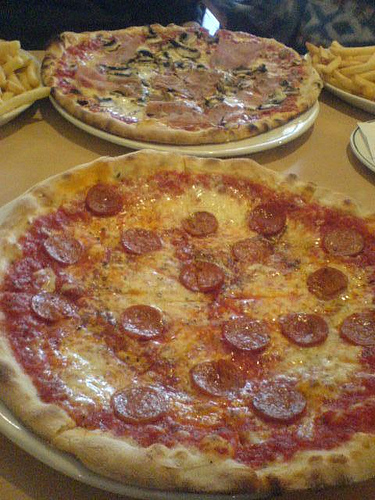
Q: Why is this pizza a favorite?
A: Pepperoni and cheese.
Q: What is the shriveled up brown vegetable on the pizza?
A: Mushrooms.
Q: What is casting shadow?
A: Plate.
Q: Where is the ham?
A: On pizza.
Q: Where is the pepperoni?
A: On pizza.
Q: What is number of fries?
A: Two.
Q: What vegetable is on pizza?
A: Mushrooms.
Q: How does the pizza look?
A: Great.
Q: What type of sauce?
A: Tomato.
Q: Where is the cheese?
A: On pizza.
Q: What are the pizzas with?
A: Fries.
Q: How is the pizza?
A: Greasy.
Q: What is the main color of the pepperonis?
A: Red.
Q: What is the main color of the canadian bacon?
A: Pink.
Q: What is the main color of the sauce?
A: Red.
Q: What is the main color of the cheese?
A: White.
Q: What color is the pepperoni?
A: Red.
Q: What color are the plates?
A: White.